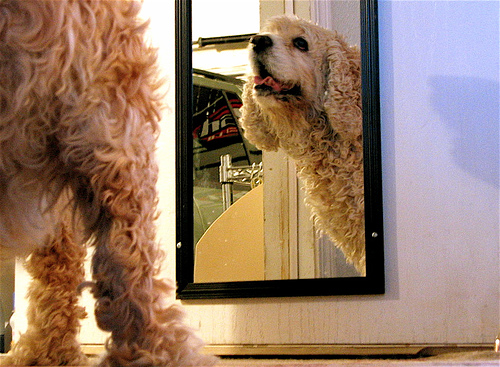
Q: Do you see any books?
A: No, there are no books.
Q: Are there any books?
A: No, there are no books.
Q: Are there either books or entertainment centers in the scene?
A: No, there are no books or entertainment centers.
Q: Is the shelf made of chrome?
A: Yes, the shelf is made of chrome.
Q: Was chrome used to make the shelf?
A: Yes, the shelf is made of chrome.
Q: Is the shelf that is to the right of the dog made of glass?
A: No, the shelf is made of chrome.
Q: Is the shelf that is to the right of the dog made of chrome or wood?
A: The shelf is made of chrome.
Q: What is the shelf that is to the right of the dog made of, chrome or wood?
A: The shelf is made of chrome.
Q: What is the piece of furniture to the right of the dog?
A: The piece of furniture is a shelf.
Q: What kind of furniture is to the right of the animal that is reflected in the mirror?
A: The piece of furniture is a shelf.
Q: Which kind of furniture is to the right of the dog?
A: The piece of furniture is a shelf.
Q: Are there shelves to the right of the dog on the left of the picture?
A: Yes, there is a shelf to the right of the dog.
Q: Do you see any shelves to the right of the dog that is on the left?
A: Yes, there is a shelf to the right of the dog.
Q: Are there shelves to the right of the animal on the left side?
A: Yes, there is a shelf to the right of the dog.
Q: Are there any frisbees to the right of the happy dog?
A: No, there is a shelf to the right of the dog.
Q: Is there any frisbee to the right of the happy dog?
A: No, there is a shelf to the right of the dog.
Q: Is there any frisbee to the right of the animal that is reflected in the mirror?
A: No, there is a shelf to the right of the dog.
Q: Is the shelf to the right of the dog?
A: Yes, the shelf is to the right of the dog.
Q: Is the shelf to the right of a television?
A: No, the shelf is to the right of the dog.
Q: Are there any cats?
A: No, there are no cats.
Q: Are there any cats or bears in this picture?
A: No, there are no cats or bears.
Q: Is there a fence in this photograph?
A: No, there are no fences.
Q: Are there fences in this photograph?
A: No, there are no fences.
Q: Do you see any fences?
A: No, there are no fences.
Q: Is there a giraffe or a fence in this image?
A: No, there are no fences or giraffes.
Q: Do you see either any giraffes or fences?
A: No, there are no fences or giraffes.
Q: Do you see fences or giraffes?
A: No, there are no fences or giraffes.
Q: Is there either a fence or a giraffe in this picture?
A: No, there are no fences or giraffes.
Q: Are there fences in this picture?
A: No, there are no fences.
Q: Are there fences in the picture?
A: No, there are no fences.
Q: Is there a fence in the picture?
A: No, there are no fences.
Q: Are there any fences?
A: No, there are no fences.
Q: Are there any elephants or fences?
A: No, there are no fences or elephants.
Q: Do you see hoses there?
A: No, there are no hoses.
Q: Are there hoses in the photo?
A: No, there are no hoses.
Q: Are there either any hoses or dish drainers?
A: No, there are no hoses or dish drainers.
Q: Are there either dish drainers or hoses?
A: No, there are no hoses or dish drainers.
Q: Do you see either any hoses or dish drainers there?
A: No, there are no hoses or dish drainers.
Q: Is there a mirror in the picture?
A: Yes, there is a mirror.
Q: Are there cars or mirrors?
A: Yes, there is a mirror.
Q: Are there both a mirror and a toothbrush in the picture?
A: No, there is a mirror but no toothbrushes.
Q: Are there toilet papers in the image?
A: No, there are no toilet papers.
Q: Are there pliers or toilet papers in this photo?
A: No, there are no toilet papers or pliers.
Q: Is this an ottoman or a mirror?
A: This is a mirror.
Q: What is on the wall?
A: The mirror is on the wall.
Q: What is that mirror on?
A: The mirror is on the wall.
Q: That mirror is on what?
A: The mirror is on the wall.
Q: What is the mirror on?
A: The mirror is on the wall.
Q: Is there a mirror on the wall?
A: Yes, there is a mirror on the wall.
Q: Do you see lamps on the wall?
A: No, there is a mirror on the wall.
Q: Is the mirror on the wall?
A: Yes, the mirror is on the wall.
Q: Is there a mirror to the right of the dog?
A: Yes, there is a mirror to the right of the dog.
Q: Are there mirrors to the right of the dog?
A: Yes, there is a mirror to the right of the dog.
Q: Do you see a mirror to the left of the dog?
A: No, the mirror is to the right of the dog.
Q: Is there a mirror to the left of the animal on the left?
A: No, the mirror is to the right of the dog.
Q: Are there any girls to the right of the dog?
A: No, there is a mirror to the right of the dog.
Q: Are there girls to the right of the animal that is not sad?
A: No, there is a mirror to the right of the dog.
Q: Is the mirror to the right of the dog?
A: Yes, the mirror is to the right of the dog.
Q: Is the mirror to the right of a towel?
A: No, the mirror is to the right of the dog.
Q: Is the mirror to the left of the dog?
A: No, the mirror is to the right of the dog.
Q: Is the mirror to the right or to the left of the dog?
A: The mirror is to the right of the dog.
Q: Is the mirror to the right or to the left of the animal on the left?
A: The mirror is to the right of the dog.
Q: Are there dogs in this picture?
A: Yes, there is a dog.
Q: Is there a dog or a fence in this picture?
A: Yes, there is a dog.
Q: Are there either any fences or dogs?
A: Yes, there is a dog.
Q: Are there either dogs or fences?
A: Yes, there is a dog.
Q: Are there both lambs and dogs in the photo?
A: No, there is a dog but no lambs.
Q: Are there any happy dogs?
A: Yes, there is a happy dog.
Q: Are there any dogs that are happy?
A: Yes, there is a dog that is happy.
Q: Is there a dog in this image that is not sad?
A: Yes, there is a happy dog.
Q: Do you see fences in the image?
A: No, there are no fences.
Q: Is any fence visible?
A: No, there are no fences.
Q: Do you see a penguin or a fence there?
A: No, there are no fences or penguins.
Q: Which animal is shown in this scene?
A: The animal is a dog.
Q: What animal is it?
A: The animal is a dog.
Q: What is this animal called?
A: That is a dog.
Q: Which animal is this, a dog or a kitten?
A: That is a dog.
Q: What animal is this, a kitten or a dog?
A: That is a dog.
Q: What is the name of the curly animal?
A: The animal is a dog.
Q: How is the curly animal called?
A: The animal is a dog.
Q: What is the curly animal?
A: The animal is a dog.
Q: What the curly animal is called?
A: The animal is a dog.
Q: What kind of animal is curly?
A: The animal is a dog.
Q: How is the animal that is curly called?
A: The animal is a dog.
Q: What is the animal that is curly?
A: The animal is a dog.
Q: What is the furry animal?
A: The animal is a dog.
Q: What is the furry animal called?
A: The animal is a dog.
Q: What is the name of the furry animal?
A: The animal is a dog.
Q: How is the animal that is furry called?
A: The animal is a dog.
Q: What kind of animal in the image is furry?
A: The animal is a dog.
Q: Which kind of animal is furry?
A: The animal is a dog.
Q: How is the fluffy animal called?
A: The animal is a dog.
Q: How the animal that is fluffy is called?
A: The animal is a dog.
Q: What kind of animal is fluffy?
A: The animal is a dog.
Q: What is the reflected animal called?
A: The animal is a dog.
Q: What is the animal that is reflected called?
A: The animal is a dog.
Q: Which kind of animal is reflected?
A: The animal is a dog.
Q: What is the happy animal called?
A: The animal is a dog.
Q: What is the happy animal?
A: The animal is a dog.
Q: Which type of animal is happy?
A: The animal is a dog.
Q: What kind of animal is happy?
A: The animal is a dog.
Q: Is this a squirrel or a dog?
A: This is a dog.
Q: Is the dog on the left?
A: Yes, the dog is on the left of the image.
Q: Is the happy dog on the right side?
A: No, the dog is on the left of the image.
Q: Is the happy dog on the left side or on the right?
A: The dog is on the left of the image.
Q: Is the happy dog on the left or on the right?
A: The dog is on the left of the image.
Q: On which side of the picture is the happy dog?
A: The dog is on the left of the image.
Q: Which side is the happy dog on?
A: The dog is on the left of the image.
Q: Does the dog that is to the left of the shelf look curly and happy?
A: Yes, the dog is curly and happy.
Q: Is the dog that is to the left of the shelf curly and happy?
A: Yes, the dog is curly and happy.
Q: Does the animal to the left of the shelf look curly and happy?
A: Yes, the dog is curly and happy.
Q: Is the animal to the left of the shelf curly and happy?
A: Yes, the dog is curly and happy.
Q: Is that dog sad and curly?
A: No, the dog is curly but happy.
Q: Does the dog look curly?
A: Yes, the dog is curly.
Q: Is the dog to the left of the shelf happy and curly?
A: Yes, the dog is happy and curly.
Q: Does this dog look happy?
A: Yes, the dog is happy.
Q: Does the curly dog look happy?
A: Yes, the dog is happy.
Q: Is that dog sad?
A: No, the dog is happy.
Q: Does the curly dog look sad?
A: No, the dog is happy.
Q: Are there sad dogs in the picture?
A: No, there is a dog but it is happy.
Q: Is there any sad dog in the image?
A: No, there is a dog but it is happy.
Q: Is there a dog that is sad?
A: No, there is a dog but it is happy.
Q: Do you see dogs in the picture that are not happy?
A: No, there is a dog but it is happy.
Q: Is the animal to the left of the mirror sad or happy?
A: The dog is happy.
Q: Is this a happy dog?
A: Yes, this is a happy dog.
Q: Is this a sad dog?
A: No, this is a happy dog.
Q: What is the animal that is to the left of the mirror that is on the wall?
A: The animal is a dog.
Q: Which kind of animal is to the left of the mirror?
A: The animal is a dog.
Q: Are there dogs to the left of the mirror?
A: Yes, there is a dog to the left of the mirror.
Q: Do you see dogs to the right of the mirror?
A: No, the dog is to the left of the mirror.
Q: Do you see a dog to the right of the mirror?
A: No, the dog is to the left of the mirror.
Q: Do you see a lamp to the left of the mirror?
A: No, there is a dog to the left of the mirror.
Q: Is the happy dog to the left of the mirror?
A: Yes, the dog is to the left of the mirror.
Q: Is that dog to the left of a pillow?
A: No, the dog is to the left of the mirror.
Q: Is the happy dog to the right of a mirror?
A: No, the dog is to the left of a mirror.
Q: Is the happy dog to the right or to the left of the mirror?
A: The dog is to the left of the mirror.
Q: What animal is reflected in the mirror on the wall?
A: The dog is reflected in the mirror.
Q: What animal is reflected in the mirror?
A: The dog is reflected in the mirror.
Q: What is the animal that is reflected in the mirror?
A: The animal is a dog.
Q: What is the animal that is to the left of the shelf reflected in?
A: The dog is reflected in the mirror.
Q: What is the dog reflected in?
A: The dog is reflected in the mirror.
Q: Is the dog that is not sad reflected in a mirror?
A: Yes, the dog is reflected in a mirror.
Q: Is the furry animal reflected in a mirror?
A: Yes, the dog is reflected in a mirror.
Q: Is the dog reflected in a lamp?
A: No, the dog is reflected in a mirror.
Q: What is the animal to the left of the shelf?
A: The animal is a dog.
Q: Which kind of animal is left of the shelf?
A: The animal is a dog.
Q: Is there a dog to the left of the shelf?
A: Yes, there is a dog to the left of the shelf.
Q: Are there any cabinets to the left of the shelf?
A: No, there is a dog to the left of the shelf.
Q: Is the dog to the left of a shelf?
A: Yes, the dog is to the left of a shelf.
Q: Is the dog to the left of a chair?
A: No, the dog is to the left of a shelf.